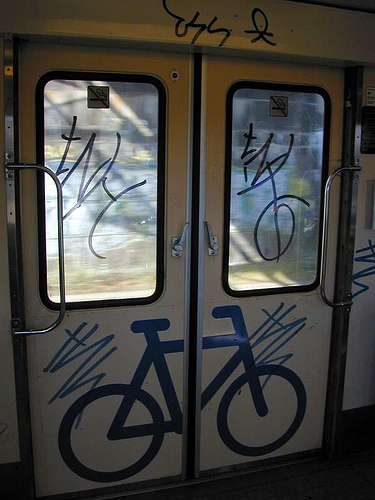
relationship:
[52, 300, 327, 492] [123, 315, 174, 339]
bicycle painted on door seat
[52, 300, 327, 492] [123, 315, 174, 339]
bicycle a painted image on door seat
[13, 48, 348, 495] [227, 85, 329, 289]
door has windows at top window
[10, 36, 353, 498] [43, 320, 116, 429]
door has bicycle painted on it doodles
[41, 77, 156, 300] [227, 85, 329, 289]
window painted with graffiti window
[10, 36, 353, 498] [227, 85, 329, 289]
door with bicycle painted at bottom of door window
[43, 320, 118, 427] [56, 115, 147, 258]
doodles at top of doors doodles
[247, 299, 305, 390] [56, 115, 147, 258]
doodles are red and blue doodles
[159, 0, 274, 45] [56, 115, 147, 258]
doodles painted over bicycle doodles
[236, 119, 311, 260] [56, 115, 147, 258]
doodles on wall next to door doodles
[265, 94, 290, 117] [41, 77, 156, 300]
label on a window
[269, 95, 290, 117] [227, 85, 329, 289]
label on a window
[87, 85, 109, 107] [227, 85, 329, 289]
label on a window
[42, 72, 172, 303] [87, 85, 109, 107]
window with label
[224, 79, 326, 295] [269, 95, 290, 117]
window with label